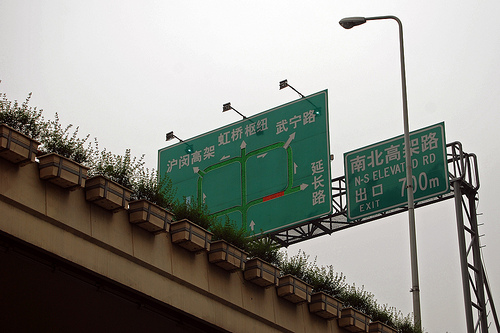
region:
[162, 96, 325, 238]
Green traffic sign with Chinese writing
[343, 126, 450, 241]
Green road sign in Chinese and English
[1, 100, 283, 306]
Plants in planters along roadway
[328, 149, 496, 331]
Metal road sign support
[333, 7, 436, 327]
Grey street lamp along roadway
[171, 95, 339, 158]
Small green lights on road sign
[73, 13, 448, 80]
Hazy grey sky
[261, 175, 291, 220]
Red mark on road sign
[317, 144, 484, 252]
Walkway behind road sign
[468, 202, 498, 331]
Ladder on metal road sign support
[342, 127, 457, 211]
green road sign in chinese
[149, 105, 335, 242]
green road sign in chinese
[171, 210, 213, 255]
box with plant on side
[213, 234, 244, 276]
box with plant on side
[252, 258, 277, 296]
box with plant on side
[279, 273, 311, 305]
box with plant on side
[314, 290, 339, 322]
box with plant on side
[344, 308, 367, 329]
box with plant on side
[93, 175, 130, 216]
box with plant on side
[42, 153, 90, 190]
box with plant on side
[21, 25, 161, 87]
the sky is gloomy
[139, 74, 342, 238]
the sign is green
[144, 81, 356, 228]
the sign is large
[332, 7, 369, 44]
the lamp is not lit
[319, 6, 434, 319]
the light pole is high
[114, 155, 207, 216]
the plants are green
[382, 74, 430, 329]
the pole is silver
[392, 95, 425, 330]
the pole is thin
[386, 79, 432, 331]
the pole is metal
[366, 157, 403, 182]
the word is white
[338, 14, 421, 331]
grey metal street light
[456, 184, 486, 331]
grey metal sign ladder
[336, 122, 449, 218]
green and white street sign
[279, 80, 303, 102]
grey metal sign light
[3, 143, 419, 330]
brown stone crossing bridge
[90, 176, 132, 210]
brown stone bridge planter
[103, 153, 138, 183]
green plants in planter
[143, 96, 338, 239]
road sign on post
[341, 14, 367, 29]
street light attached to post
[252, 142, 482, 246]
grey metal sign bridge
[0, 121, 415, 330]
concrete highway overpass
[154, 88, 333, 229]
green highway sign with map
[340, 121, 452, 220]
green highway sign with Chinese and English characters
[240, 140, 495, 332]
metal scaffold holding signs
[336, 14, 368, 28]
lamp of streetlight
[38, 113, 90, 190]
planter box on highway overpass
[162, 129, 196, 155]
light to illuminate road sign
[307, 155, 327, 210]
vertical Chinese characters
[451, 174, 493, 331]
ladder to access highway signs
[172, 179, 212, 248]
planter box on overpass